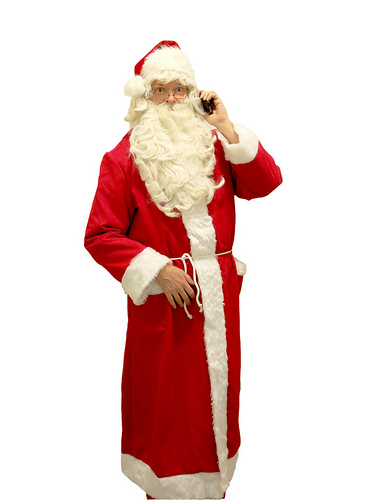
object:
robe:
[83, 123, 282, 500]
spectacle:
[147, 81, 189, 112]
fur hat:
[124, 40, 199, 99]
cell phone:
[201, 98, 213, 115]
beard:
[129, 95, 225, 218]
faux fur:
[120, 205, 240, 500]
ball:
[124, 75, 145, 98]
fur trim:
[121, 247, 173, 306]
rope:
[169, 250, 232, 319]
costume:
[83, 39, 282, 500]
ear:
[192, 87, 200, 97]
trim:
[180, 204, 229, 492]